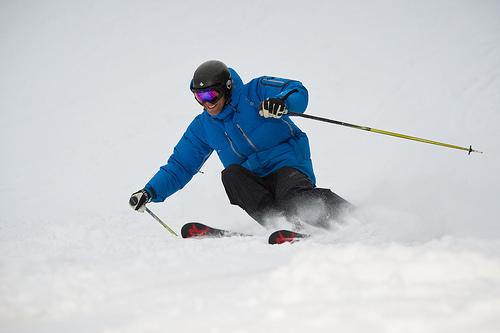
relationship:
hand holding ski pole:
[257, 96, 288, 119] [258, 98, 483, 164]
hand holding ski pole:
[128, 190, 152, 212] [125, 193, 179, 235]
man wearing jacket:
[126, 59, 371, 229] [143, 64, 317, 206]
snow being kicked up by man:
[293, 184, 496, 252] [126, 59, 371, 229]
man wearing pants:
[126, 59, 371, 229] [219, 164, 374, 231]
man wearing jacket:
[126, 59, 371, 229] [140, 71, 310, 207]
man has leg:
[126, 59, 371, 229] [220, 164, 292, 234]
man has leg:
[126, 59, 371, 229] [256, 161, 356, 238]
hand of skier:
[259, 91, 288, 115] [118, 50, 385, 235]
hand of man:
[122, 187, 156, 214] [126, 59, 371, 229]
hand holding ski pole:
[126, 190, 156, 219] [123, 190, 185, 244]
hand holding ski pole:
[257, 96, 288, 119] [260, 99, 482, 156]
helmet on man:
[188, 59, 233, 116] [126, 59, 371, 229]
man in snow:
[126, 59, 371, 229] [1, 5, 479, 329]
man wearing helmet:
[126, 59, 371, 229] [181, 55, 234, 118]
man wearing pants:
[126, 59, 371, 229] [205, 158, 381, 232]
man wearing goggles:
[118, 53, 386, 229] [185, 85, 228, 103]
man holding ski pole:
[118, 53, 386, 229] [143, 204, 178, 237]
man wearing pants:
[118, 53, 386, 229] [221, 157, 375, 235]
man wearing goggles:
[126, 59, 371, 229] [181, 77, 230, 108]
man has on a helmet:
[118, 53, 386, 229] [186, 49, 237, 111]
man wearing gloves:
[118, 53, 386, 229] [106, 95, 298, 221]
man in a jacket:
[126, 59, 371, 229] [133, 69, 318, 199]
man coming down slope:
[126, 59, 371, 229] [4, 6, 464, 310]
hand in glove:
[253, 93, 295, 119] [250, 89, 293, 125]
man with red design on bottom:
[126, 59, 371, 229] [183, 215, 301, 296]